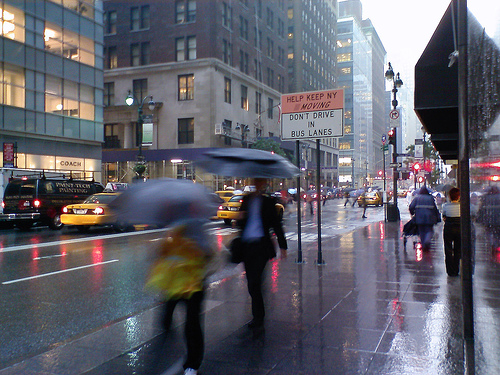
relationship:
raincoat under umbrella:
[144, 231, 216, 295] [108, 173, 227, 230]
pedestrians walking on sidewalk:
[113, 178, 290, 371] [1, 198, 496, 370]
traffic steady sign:
[307, 175, 415, 205] [276, 85, 346, 140]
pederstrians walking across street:
[297, 180, 384, 222] [1, 190, 389, 358]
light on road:
[376, 63, 402, 219] [0, 166, 500, 375]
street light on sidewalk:
[120, 88, 159, 177] [288, 144, 498, 297]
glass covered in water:
[431, 2, 498, 373] [472, 26, 483, 91]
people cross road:
[146, 163, 327, 340] [0, 166, 500, 375]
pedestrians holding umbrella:
[137, 200, 222, 374] [187, 128, 288, 183]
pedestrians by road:
[137, 200, 222, 374] [5, 166, 432, 364]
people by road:
[225, 174, 290, 329] [12, 231, 123, 328]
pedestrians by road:
[137, 200, 222, 374] [12, 231, 123, 328]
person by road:
[322, 189, 327, 203] [12, 231, 123, 328]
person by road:
[343, 195, 350, 205] [12, 231, 123, 328]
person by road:
[305, 195, 313, 212] [12, 231, 123, 328]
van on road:
[3, 173, 110, 234] [0, 166, 500, 373]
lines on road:
[6, 251, 129, 284] [33, 284, 118, 332]